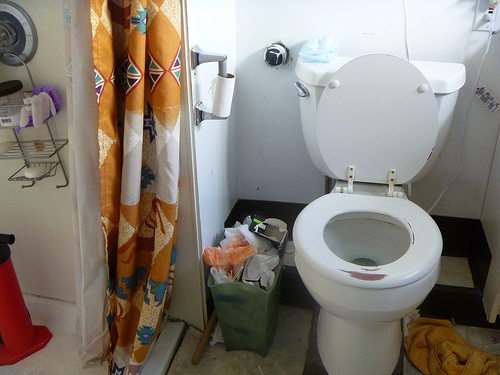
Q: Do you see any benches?
A: No, there are no benches.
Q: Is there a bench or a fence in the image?
A: No, there are no benches or fences.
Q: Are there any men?
A: No, there are no men.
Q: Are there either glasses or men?
A: No, there are no men or glasses.